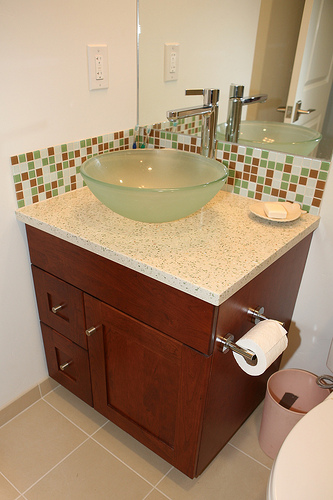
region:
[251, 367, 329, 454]
a pink wastepaper basket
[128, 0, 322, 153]
a bathroom mirror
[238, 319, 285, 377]
roll of toilet paper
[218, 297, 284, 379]
toilet paper and chrome dispenser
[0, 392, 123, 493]
tiled floor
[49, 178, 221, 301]
granite covered vanity countertop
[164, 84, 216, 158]
chrome water faucet and handle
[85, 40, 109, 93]
rectangular electrical outlet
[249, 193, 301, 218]
bar of soap in dish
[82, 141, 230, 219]
a glass bathroom sink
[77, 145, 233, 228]
Glass bowl sink sitting on vanity.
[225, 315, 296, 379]
Toilet paper mounted on side of vanity.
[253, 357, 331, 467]
Pink trash can between vanity and toilet.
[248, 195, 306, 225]
Soap sitting in dish on vanity.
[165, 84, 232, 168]
Faucet over glass bowl sink.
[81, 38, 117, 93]
Electrical outlet on wall.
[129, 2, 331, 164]
Mirror above marble top vanity.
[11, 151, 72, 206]
White, green and brown tile back splash around vanity.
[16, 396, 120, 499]
A beige tiled floor.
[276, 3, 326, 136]
Reflection of bathroom door in mirror.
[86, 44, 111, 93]
Electrical outlet on the side wall.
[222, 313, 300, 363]
Toilet paper roll mounted on the brown wood.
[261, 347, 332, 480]
Peach trash can on the side of the toilet.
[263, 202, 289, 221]
Bar of soap on the dish.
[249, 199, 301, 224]
Dish the bar of soap is placed on.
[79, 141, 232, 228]
Bowl used as a sink.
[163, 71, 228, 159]
Faucet attached to the mirror.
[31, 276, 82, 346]
Top drawer on the left side of the cabinet.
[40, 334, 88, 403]
Bottom drawer on the left side of the cabinet.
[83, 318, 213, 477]
Door in the center of the cabinet.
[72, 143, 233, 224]
A bowl is sitting on a bathroom sink.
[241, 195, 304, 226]
A bar of soap is sitting in a soap-dish.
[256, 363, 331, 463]
A wastebasket is sitting on the floor.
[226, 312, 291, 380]
A roll of toilet paper is next to the toilet.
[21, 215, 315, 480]
The color of the sinks base is red.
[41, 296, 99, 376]
Three silver knobs are on the base of the sink.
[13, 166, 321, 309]
The top of the sink is speckled.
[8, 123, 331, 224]
The back-splash's color is red, green, and white.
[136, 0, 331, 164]
A mirror is behind the sink.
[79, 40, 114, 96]
An outlet is next to the sink.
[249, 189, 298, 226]
small dish with bar of soap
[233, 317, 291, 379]
toilet paper on roll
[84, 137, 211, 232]
bowl sink on counter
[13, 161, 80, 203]
tiled border around sink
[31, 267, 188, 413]
front of cabinet with doors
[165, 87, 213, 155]
silver water faucet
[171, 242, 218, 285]
marble sink countertop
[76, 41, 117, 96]
electric outlet on wall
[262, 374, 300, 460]
pink garbage can on floor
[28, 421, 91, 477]
tan tile on floor